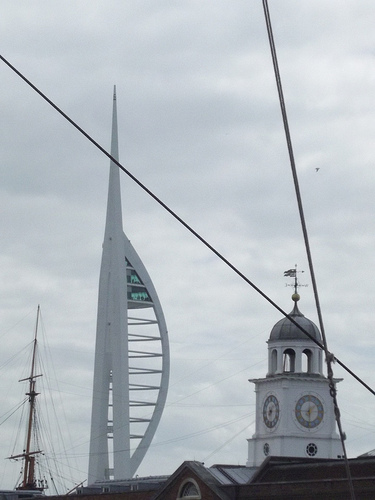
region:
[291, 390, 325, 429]
clock on side of tower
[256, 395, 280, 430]
clock on side of tower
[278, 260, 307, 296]
weather vane on top of tower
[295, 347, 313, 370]
arch on side of tower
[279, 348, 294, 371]
arch on side of tower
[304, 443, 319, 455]
small circle on side of tower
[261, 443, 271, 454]
small circle on side of tower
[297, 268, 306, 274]
arrow on side of weather vane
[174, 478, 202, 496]
small circle on house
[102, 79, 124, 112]
point on top of structure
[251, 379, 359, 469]
large clock on building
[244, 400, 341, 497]
large clock on building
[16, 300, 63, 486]
the mast of a boat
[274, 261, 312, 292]
a weather vane on a building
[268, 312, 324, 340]
a dome on a building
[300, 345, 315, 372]
an arched opening under a dome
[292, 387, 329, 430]
a clock in a cupola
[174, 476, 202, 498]
an arched window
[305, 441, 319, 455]
a round window in te base of a cupola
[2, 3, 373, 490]
a cloudy sky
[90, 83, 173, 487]
a large decorative statue of a sail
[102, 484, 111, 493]
a window on a building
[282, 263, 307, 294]
a compass on the spire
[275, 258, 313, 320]
the spire on the dome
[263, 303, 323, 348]
the dome of the tower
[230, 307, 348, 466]
A bell tower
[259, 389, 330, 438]
clocks on the tower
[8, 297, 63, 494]
sails of the boat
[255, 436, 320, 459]
windows on the white wall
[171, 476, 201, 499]
window on the building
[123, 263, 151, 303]
people in the window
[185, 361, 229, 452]
wires hanging in the sky